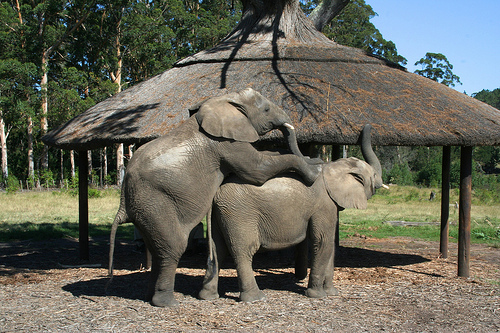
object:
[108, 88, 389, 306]
elephants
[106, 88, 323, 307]
elephant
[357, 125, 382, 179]
trunk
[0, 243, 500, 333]
woodchips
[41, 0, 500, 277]
structure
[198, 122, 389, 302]
elephant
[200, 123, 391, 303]
female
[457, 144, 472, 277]
pole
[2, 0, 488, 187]
area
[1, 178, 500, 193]
fence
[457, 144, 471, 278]
post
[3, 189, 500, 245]
grass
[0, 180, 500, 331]
enclosure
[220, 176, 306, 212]
back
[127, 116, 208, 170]
back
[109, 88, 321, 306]
male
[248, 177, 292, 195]
patch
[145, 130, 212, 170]
patch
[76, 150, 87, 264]
poles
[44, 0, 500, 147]
straw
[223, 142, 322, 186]
leg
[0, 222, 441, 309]
shadow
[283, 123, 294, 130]
tusks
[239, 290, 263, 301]
foot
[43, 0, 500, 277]
hut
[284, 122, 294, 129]
tusk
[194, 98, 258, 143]
ear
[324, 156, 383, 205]
elephant's head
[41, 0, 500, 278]
shelter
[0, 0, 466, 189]
trees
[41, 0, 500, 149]
roof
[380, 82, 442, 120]
natural resources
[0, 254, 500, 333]
bark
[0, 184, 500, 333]
compound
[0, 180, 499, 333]
ground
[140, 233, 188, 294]
legs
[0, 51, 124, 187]
trunks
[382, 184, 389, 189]
tusk